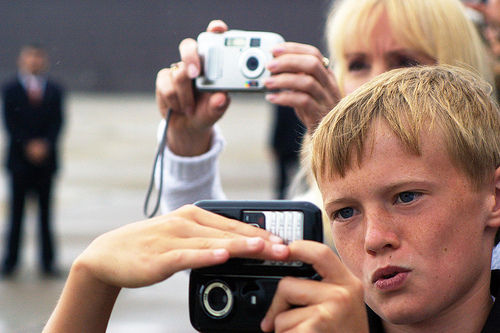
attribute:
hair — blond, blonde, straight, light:
[320, 3, 499, 92]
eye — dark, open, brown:
[349, 60, 368, 72]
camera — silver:
[192, 29, 285, 94]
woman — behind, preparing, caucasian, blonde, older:
[164, 5, 488, 214]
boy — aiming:
[62, 69, 496, 331]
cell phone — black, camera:
[189, 198, 325, 331]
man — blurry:
[4, 47, 80, 278]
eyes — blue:
[337, 193, 422, 219]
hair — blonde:
[306, 63, 498, 199]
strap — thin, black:
[145, 105, 182, 217]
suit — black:
[5, 72, 67, 269]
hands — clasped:
[49, 203, 373, 328]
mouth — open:
[370, 264, 407, 289]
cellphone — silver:
[234, 205, 311, 266]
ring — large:
[170, 61, 184, 75]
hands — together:
[25, 138, 47, 162]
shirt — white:
[159, 122, 358, 235]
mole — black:
[388, 253, 396, 260]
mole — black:
[445, 249, 450, 254]